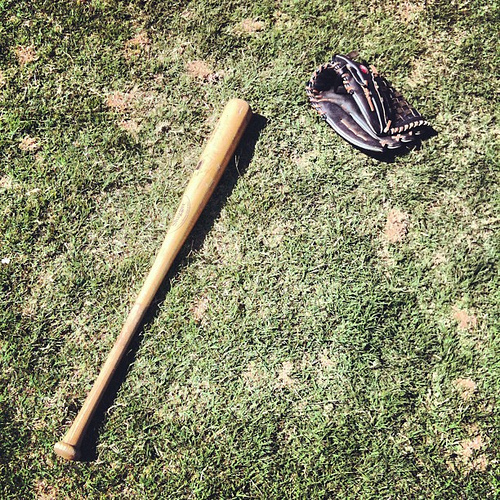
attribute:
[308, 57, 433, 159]
baseball glove — black, leather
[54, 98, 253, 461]
baseball bat — wooden, brown, long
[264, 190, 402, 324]
grass — green, patchy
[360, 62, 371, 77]
label — red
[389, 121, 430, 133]
stitching — beige